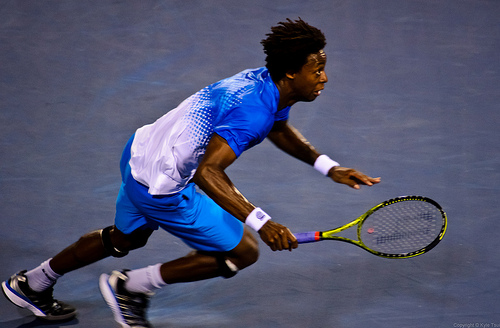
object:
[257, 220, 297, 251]
hand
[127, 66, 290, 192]
blue outfit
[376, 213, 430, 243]
logo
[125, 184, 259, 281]
leg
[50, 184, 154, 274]
leg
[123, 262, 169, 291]
sock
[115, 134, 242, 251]
shorts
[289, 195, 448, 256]
racquet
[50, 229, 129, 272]
calf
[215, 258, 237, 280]
band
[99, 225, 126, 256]
band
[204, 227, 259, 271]
knee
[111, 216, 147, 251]
knee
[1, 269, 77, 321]
shoe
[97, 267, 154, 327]
shoe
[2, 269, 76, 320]
feet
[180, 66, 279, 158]
checkerboard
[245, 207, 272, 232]
band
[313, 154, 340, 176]
band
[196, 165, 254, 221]
muscle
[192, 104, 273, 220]
arm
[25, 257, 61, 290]
sock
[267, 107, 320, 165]
arm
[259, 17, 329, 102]
head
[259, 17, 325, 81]
hair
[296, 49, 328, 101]
face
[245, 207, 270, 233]
wrist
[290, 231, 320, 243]
handle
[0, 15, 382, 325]
athlete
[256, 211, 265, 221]
logo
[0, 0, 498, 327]
court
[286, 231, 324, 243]
wrap